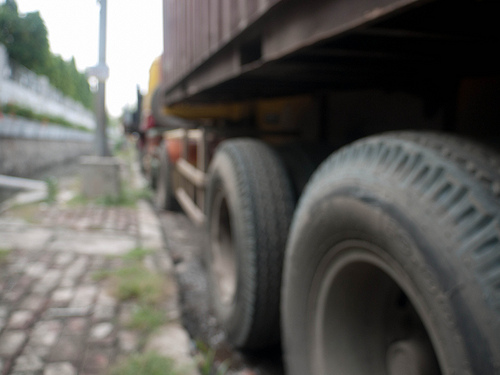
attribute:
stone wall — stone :
[0, 59, 96, 174]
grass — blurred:
[110, 246, 175, 343]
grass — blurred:
[49, 180, 151, 207]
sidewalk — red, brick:
[58, 218, 141, 371]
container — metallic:
[163, 0, 496, 110]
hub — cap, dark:
[213, 208, 238, 308]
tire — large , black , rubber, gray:
[281, 135, 498, 369]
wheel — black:
[203, 138, 285, 353]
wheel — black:
[281, 131, 498, 374]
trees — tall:
[0, 6, 94, 108]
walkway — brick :
[3, 148, 178, 373]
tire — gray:
[186, 132, 300, 359]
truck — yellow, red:
[122, 55, 171, 150]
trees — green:
[5, 2, 97, 97]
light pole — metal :
[92, 1, 115, 156]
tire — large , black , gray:
[199, 134, 298, 365]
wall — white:
[28, 58, 112, 148]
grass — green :
[119, 235, 172, 374]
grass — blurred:
[98, 191, 135, 208]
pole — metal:
[97, 2, 110, 154]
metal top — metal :
[157, 2, 349, 112]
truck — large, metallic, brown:
[160, 2, 496, 370]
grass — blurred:
[78, 115, 193, 318]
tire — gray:
[154, 145, 174, 210]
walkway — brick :
[5, 137, 200, 374]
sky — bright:
[15, 1, 165, 121]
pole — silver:
[93, 2, 115, 156]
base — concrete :
[72, 140, 133, 220]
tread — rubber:
[298, 116, 498, 283]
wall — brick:
[0, 45, 98, 214]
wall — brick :
[0, 60, 103, 214]